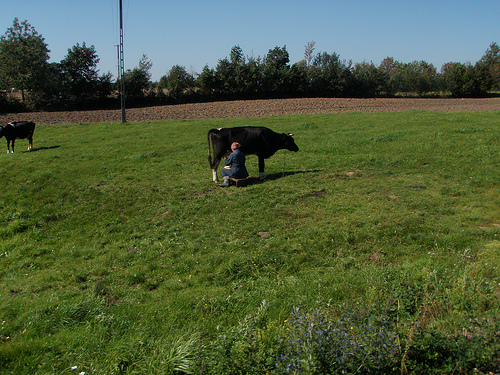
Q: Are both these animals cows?
A: Yes, all the animals are cows.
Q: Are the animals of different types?
A: No, all the animals are cows.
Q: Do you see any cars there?
A: No, there are no cars.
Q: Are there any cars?
A: No, there are no cars.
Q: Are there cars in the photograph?
A: No, there are no cars.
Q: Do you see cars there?
A: No, there are no cars.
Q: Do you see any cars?
A: No, there are no cars.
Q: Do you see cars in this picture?
A: No, there are no cars.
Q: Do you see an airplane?
A: No, there are no airplanes.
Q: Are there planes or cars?
A: No, there are no planes or cars.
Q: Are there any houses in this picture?
A: No, there are no houses.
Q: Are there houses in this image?
A: No, there are no houses.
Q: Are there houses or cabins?
A: No, there are no houses or cabins.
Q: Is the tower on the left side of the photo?
A: Yes, the tower is on the left of the image.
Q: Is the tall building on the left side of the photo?
A: Yes, the tower is on the left of the image.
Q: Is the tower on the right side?
A: No, the tower is on the left of the image.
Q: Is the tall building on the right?
A: No, the tower is on the left of the image.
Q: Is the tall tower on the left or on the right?
A: The tower is on the left of the image.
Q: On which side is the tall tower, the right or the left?
A: The tower is on the left of the image.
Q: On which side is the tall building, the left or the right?
A: The tower is on the left of the image.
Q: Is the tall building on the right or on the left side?
A: The tower is on the left of the image.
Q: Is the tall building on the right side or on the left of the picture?
A: The tower is on the left of the image.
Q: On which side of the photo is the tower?
A: The tower is on the left of the image.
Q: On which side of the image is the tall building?
A: The tower is on the left of the image.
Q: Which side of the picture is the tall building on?
A: The tower is on the left of the image.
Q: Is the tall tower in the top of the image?
A: Yes, the tower is in the top of the image.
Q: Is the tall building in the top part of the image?
A: Yes, the tower is in the top of the image.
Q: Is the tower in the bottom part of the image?
A: No, the tower is in the top of the image.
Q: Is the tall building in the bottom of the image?
A: No, the tower is in the top of the image.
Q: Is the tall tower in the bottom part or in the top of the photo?
A: The tower is in the top of the image.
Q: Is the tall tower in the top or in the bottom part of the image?
A: The tower is in the top of the image.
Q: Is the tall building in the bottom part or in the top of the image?
A: The tower is in the top of the image.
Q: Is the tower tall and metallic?
A: Yes, the tower is tall and metallic.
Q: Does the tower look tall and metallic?
A: Yes, the tower is tall and metallic.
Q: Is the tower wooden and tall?
A: No, the tower is tall but metallic.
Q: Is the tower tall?
A: Yes, the tower is tall.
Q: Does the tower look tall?
A: Yes, the tower is tall.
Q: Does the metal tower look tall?
A: Yes, the tower is tall.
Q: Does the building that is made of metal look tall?
A: Yes, the tower is tall.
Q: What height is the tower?
A: The tower is tall.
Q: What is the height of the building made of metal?
A: The tower is tall.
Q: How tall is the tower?
A: The tower is tall.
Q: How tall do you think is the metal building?
A: The tower is tall.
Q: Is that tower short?
A: No, the tower is tall.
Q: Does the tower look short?
A: No, the tower is tall.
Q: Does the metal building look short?
A: No, the tower is tall.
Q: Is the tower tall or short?
A: The tower is tall.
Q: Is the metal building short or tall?
A: The tower is tall.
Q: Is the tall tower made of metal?
A: Yes, the tower is made of metal.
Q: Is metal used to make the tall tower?
A: Yes, the tower is made of metal.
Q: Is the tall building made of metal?
A: Yes, the tower is made of metal.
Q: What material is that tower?
A: The tower is made of metal.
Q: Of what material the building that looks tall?
A: The tower is made of metal.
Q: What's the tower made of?
A: The tower is made of metal.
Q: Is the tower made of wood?
A: No, the tower is made of metal.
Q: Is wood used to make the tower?
A: No, the tower is made of metal.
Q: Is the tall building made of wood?
A: No, the tower is made of metal.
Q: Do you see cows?
A: Yes, there is a cow.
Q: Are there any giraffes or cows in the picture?
A: Yes, there is a cow.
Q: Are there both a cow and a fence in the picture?
A: Yes, there are both a cow and a fence.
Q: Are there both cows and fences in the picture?
A: Yes, there are both a cow and a fence.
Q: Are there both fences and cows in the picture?
A: Yes, there are both a cow and a fence.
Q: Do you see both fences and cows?
A: Yes, there are both a cow and a fence.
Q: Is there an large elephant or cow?
A: Yes, there is a large cow.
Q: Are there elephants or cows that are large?
A: Yes, the cow is large.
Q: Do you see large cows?
A: Yes, there is a large cow.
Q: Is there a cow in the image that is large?
A: Yes, there is a cow that is large.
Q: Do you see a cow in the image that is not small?
A: Yes, there is a large cow.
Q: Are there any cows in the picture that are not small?
A: Yes, there is a large cow.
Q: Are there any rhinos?
A: No, there are no rhinos.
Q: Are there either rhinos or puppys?
A: No, there are no rhinos or puppys.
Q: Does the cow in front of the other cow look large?
A: Yes, the cow is large.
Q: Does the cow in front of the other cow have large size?
A: Yes, the cow is large.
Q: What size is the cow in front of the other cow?
A: The cow is large.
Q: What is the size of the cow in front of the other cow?
A: The cow is large.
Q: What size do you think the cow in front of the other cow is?
A: The cow is large.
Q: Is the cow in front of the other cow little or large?
A: The cow is large.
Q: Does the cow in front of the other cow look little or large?
A: The cow is large.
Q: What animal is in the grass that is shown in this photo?
A: The animal is a cow.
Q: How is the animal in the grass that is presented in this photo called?
A: The animal is a cow.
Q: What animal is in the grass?
A: The animal is a cow.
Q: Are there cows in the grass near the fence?
A: Yes, there is a cow in the grass.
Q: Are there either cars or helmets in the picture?
A: No, there are no cars or helmets.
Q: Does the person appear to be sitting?
A: Yes, the person is sitting.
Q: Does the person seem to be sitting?
A: Yes, the person is sitting.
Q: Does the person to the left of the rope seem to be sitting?
A: Yes, the person is sitting.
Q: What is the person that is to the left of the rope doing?
A: The person is sitting.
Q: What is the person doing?
A: The person is sitting.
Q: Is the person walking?
A: No, the person is sitting.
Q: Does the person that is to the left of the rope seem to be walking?
A: No, the person is sitting.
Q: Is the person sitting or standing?
A: The person is sitting.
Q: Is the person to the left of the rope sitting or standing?
A: The person is sitting.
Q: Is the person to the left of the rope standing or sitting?
A: The person is sitting.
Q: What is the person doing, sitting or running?
A: The person is sitting.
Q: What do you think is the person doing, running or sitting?
A: The person is sitting.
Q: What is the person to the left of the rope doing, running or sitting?
A: The person is sitting.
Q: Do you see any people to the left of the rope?
A: Yes, there is a person to the left of the rope.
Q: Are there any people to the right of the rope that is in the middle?
A: No, the person is to the left of the rope.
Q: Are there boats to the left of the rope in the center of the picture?
A: No, there is a person to the left of the rope.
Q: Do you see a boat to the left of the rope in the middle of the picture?
A: No, there is a person to the left of the rope.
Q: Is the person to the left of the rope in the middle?
A: Yes, the person is to the left of the rope.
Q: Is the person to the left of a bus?
A: No, the person is to the left of the rope.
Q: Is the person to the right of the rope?
A: No, the person is to the left of the rope.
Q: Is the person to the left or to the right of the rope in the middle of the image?
A: The person is to the left of the rope.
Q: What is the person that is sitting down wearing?
A: The person is wearing a jacket.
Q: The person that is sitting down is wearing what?
A: The person is wearing a jacket.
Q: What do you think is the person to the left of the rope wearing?
A: The person is wearing a jacket.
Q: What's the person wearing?
A: The person is wearing a jacket.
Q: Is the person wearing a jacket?
A: Yes, the person is wearing a jacket.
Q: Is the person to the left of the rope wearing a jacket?
A: Yes, the person is wearing a jacket.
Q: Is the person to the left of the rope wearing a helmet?
A: No, the person is wearing a jacket.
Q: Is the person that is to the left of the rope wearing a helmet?
A: No, the person is wearing a jacket.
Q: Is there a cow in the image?
A: Yes, there is a cow.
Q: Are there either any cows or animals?
A: Yes, there is a cow.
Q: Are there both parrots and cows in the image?
A: No, there is a cow but no parrots.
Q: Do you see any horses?
A: No, there are no horses.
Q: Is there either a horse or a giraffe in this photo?
A: No, there are no horses or giraffes.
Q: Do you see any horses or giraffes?
A: No, there are no horses or giraffes.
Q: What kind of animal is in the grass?
A: The animal is a cow.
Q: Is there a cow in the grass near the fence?
A: Yes, there is a cow in the grass.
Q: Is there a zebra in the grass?
A: No, there is a cow in the grass.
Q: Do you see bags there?
A: No, there are no bags.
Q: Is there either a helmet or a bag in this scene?
A: No, there are no bags or helmets.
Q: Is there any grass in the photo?
A: Yes, there is grass.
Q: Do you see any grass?
A: Yes, there is grass.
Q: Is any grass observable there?
A: Yes, there is grass.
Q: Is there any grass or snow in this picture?
A: Yes, there is grass.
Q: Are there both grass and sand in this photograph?
A: No, there is grass but no sand.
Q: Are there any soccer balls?
A: No, there are no soccer balls.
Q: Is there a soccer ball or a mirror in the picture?
A: No, there are no soccer balls or mirrors.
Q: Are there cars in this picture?
A: No, there are no cars.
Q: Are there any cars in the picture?
A: No, there are no cars.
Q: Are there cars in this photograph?
A: No, there are no cars.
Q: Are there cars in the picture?
A: No, there are no cars.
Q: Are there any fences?
A: Yes, there is a fence.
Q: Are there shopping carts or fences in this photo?
A: Yes, there is a fence.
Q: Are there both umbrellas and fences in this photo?
A: No, there is a fence but no umbrellas.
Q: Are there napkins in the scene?
A: No, there are no napkins.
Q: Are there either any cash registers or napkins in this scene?
A: No, there are no napkins or cash registers.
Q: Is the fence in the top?
A: Yes, the fence is in the top of the image.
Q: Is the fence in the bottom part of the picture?
A: No, the fence is in the top of the image.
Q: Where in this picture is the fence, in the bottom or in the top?
A: The fence is in the top of the image.